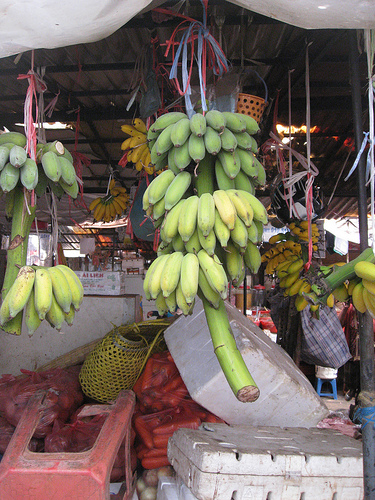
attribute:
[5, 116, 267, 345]
bananas — green, hanging, unripe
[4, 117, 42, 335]
stalk — long, green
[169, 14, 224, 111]
ribbon — blue, red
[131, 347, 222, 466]
carrots — bagged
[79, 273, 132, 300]
sign — red, white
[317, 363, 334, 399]
seat — blue, white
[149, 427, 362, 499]
crate — gray, styrofoam, white, large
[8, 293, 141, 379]
wall — gray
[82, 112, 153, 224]
bananas — yellow, ripe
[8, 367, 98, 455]
bag — plastic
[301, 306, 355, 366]
bag — plaid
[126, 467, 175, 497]
onions — yellow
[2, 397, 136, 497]
step stool — overturned, red, plastic, flipped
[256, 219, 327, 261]
menu — white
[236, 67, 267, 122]
basket — brown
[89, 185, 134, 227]
bunches — small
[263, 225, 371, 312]
bananas — yellow, bunched, hanging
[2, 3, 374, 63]
net — rolled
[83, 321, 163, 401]
bag — yellow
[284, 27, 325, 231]
ribbon — hanging